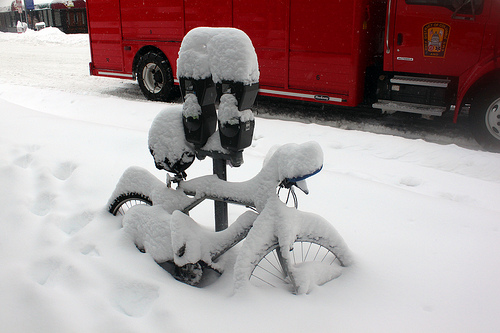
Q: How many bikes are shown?
A: One.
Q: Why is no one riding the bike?
A: It's buried in snow.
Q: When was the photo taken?
A: Winter time.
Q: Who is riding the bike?
A: No one.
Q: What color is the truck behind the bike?
A: Red.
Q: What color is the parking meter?
A: Black.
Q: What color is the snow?
A: White.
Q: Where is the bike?
A: Near the parking meter.